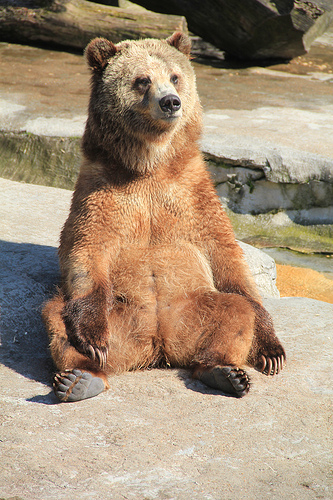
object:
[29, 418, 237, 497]
floor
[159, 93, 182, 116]
nose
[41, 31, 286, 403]
bear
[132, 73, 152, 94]
eye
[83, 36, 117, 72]
ear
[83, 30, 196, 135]
head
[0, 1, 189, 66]
log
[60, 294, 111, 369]
paw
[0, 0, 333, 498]
ground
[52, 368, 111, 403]
foot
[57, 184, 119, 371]
arm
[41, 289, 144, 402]
leg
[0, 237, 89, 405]
shadow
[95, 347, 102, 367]
finger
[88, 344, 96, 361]
claws